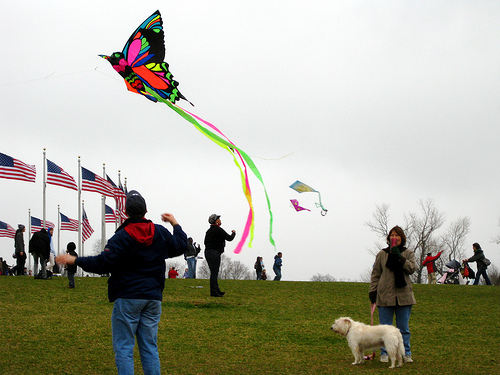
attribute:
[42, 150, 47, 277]
pole — metal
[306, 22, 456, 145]
skies — cloudy, large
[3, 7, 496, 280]
skies — cloudy, Large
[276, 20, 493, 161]
sky — large, cloudy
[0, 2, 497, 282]
sky — cloudy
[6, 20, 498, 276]
clouds — large